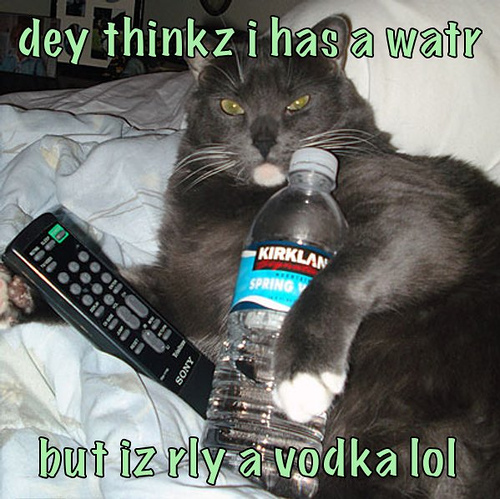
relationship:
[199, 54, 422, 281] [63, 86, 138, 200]
cat on bed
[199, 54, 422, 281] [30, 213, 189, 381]
cat with remote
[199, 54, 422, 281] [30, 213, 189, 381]
cat has remote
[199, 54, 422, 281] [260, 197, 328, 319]
cat with bottle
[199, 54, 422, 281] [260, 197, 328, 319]
cat holding bottle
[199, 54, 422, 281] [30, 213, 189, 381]
cat holding remote